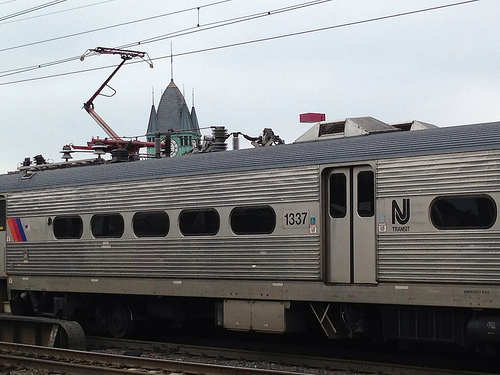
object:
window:
[87, 208, 127, 240]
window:
[132, 206, 171, 240]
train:
[0, 116, 499, 351]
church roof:
[141, 44, 204, 138]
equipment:
[64, 42, 159, 159]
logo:
[390, 197, 411, 225]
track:
[0, 323, 213, 375]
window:
[324, 170, 347, 218]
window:
[353, 163, 376, 218]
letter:
[391, 226, 410, 232]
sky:
[0, 0, 499, 168]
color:
[5, 216, 27, 244]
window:
[47, 210, 86, 242]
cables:
[0, 0, 474, 89]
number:
[285, 211, 308, 226]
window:
[230, 206, 278, 235]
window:
[427, 192, 500, 232]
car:
[0, 116, 500, 358]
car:
[22, 103, 310, 316]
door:
[316, 156, 379, 289]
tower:
[139, 44, 210, 158]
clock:
[154, 136, 180, 159]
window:
[179, 206, 222, 239]